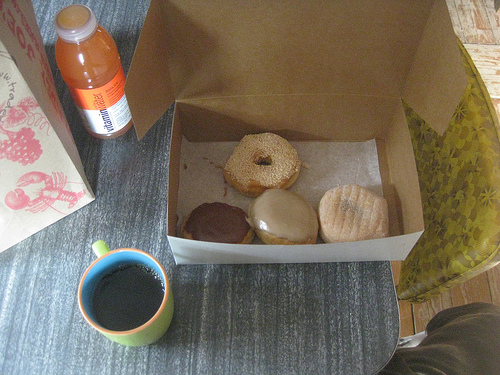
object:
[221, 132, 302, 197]
doughnut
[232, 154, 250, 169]
sprinkles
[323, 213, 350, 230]
sugar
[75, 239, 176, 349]
cup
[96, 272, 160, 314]
coffee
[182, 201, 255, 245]
doughnut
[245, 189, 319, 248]
donut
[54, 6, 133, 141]
bottle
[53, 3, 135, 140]
drinking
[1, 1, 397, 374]
table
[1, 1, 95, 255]
bag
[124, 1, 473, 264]
box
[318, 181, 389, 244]
doughnuts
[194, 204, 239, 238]
chocolate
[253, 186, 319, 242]
vanilla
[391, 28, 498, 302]
chair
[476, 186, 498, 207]
design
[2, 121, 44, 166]
design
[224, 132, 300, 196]
coconut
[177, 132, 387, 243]
paper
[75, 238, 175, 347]
drink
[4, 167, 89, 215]
lobster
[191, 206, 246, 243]
icing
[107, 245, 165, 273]
rim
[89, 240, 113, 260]
handle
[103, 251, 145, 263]
blue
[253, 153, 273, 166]
hole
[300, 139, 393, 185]
tissue paper